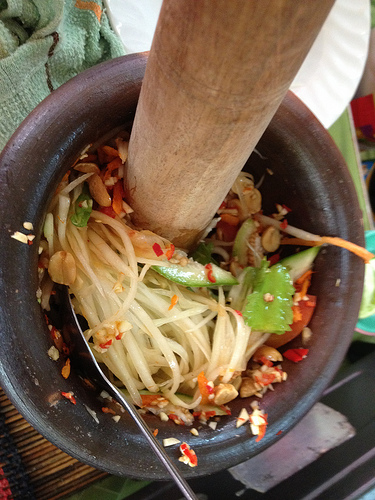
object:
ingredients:
[34, 153, 321, 429]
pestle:
[112, 1, 336, 267]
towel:
[0, 0, 125, 149]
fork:
[53, 276, 200, 499]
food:
[34, 132, 321, 437]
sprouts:
[27, 200, 292, 401]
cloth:
[0, 2, 123, 156]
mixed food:
[15, 134, 375, 453]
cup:
[0, 48, 368, 477]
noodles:
[68, 210, 241, 387]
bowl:
[3, 49, 368, 476]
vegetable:
[47, 143, 324, 430]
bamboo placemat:
[0, 390, 108, 498]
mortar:
[0, 52, 366, 478]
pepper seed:
[85, 155, 130, 204]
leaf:
[242, 259, 296, 338]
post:
[122, 0, 335, 250]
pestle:
[125, 1, 352, 253]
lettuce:
[148, 248, 239, 287]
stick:
[123, 0, 336, 255]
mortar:
[118, 0, 338, 246]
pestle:
[0, 43, 375, 488]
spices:
[169, 243, 283, 395]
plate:
[288, 2, 372, 131]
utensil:
[62, 286, 197, 499]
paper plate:
[106, 0, 370, 129]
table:
[0, 337, 373, 497]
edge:
[66, 292, 125, 391]